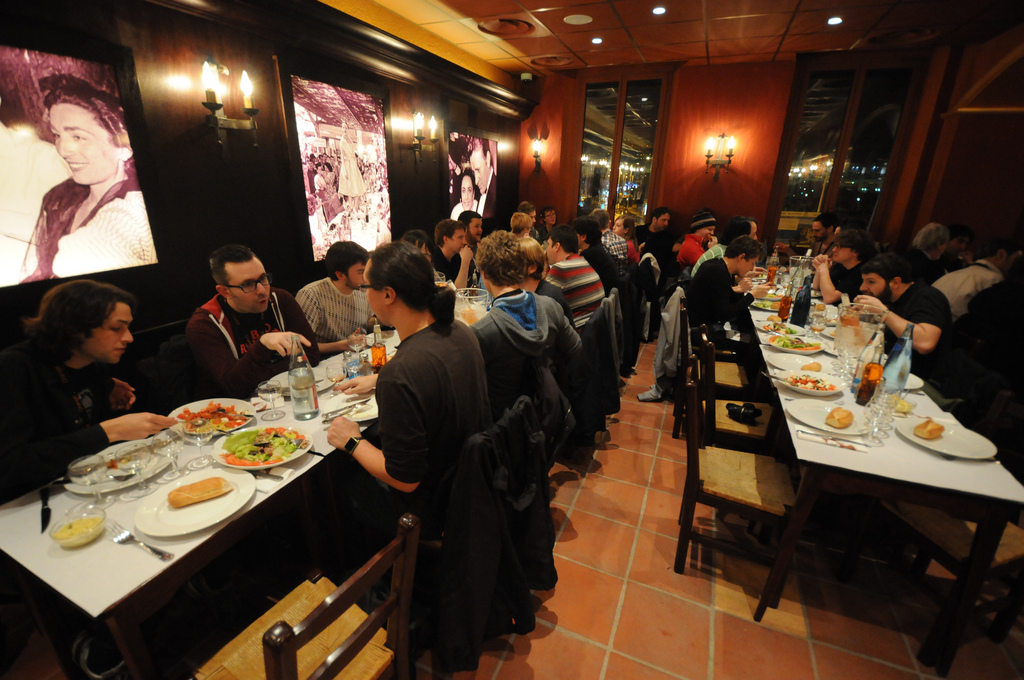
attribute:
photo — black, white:
[14, 52, 164, 286]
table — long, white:
[71, 170, 609, 631]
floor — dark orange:
[614, 461, 688, 675]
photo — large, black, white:
[0, 50, 197, 288]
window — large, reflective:
[618, 78, 662, 208]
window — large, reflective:
[577, 80, 616, 238]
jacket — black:
[179, 296, 346, 376]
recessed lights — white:
[575, 5, 871, 53]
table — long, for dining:
[742, 307, 946, 541]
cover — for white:
[789, 418, 848, 449]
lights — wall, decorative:
[685, 107, 765, 222]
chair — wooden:
[186, 506, 424, 677]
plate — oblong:
[130, 463, 256, 543]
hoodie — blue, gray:
[469, 290, 586, 433]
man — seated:
[180, 242, 317, 400]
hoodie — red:
[176, 282, 319, 397]